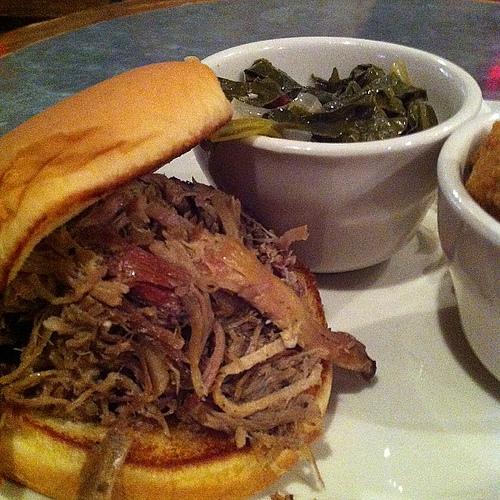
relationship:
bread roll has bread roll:
[0, 54, 374, 500] [0, 54, 374, 500]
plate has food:
[0, 89, 500, 497] [0, 53, 377, 498]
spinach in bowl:
[236, 68, 417, 132] [198, 36, 489, 274]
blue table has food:
[50, 36, 125, 76] [56, 185, 325, 452]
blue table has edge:
[0, 4, 500, 131] [10, 24, 40, 42]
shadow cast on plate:
[368, 316, 461, 425] [152, 97, 497, 499]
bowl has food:
[198, 36, 489, 274] [207, 52, 499, 221]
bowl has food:
[435, 112, 498, 384] [0, 43, 499, 500]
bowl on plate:
[198, 36, 489, 274] [0, 89, 500, 497]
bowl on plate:
[435, 112, 498, 384] [0, 89, 500, 497]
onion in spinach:
[230, 90, 325, 120] [213, 39, 443, 135]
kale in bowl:
[244, 72, 421, 132] [181, 31, 468, 283]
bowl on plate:
[189, 106, 466, 281] [166, 144, 482, 496]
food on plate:
[0, 43, 499, 500] [345, 295, 472, 477]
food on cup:
[0, 43, 499, 500] [176, 35, 483, 275]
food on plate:
[0, 54, 499, 499] [136, 60, 476, 499]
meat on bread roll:
[73, 225, 378, 440] [0, 54, 374, 500]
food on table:
[0, 54, 499, 499] [12, 31, 494, 196]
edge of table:
[5, 9, 122, 51] [6, 10, 491, 401]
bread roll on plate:
[0, 54, 374, 500] [121, 82, 496, 498]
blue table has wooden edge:
[0, 4, 500, 131] [1, 0, 208, 62]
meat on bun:
[22, 228, 304, 429] [0, 48, 258, 262]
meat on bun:
[22, 228, 304, 429] [0, 410, 332, 498]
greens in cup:
[225, 40, 440, 155] [238, 155, 414, 251]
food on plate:
[0, 43, 499, 500] [366, 265, 469, 331]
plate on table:
[366, 265, 469, 331] [11, 3, 201, 97]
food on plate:
[0, 43, 499, 500] [330, 284, 496, 476]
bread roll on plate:
[0, 54, 374, 500] [152, 97, 497, 499]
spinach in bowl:
[197, 55, 437, 142] [198, 36, 489, 274]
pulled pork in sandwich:
[12, 166, 384, 475] [8, 63, 349, 499]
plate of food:
[0, 89, 500, 497] [0, 54, 499, 499]